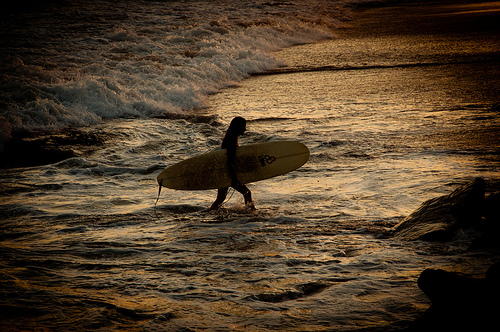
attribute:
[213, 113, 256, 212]
person — carrying, tethered, walking, leaning, holding, exiting, wet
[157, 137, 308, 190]
surfing — under, yellow, white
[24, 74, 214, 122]
waves — crashing, white, beside, breaking, rough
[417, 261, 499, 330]
rocks — on, black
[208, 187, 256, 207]
knees — below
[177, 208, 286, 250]
water — wet, not clear, splashing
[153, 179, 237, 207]
strap — hanging, black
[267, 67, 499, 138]
water — calm, hue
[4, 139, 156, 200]
water — swirled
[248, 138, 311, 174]
board — higher, long, yellow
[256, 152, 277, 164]
logo — black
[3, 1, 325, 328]
ocean — bigh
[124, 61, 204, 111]
foam — white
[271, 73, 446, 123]
light — reflecting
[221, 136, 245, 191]
arm — holding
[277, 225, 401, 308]
ripples — soft